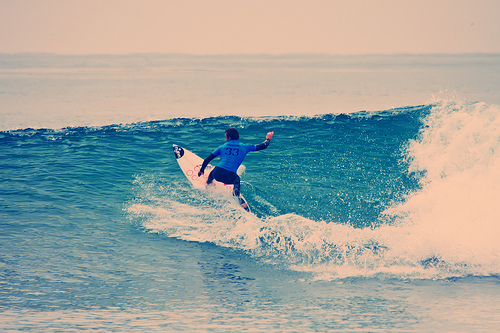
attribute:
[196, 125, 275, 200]
man — wearing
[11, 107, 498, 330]
water — blue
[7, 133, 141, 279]
ocean — white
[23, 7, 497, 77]
sky — hazy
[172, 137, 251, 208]
surfboard — white 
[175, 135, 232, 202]
surfboard — white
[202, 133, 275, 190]
shirt — blue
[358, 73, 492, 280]
wave — blue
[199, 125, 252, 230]
man — on surfboard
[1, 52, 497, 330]
ocean — blue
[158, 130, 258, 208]
surfboard — white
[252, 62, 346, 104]
water — blue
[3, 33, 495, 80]
horizon — white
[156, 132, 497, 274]
waves — white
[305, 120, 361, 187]
water — white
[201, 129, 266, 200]
wetsuit — blue and black